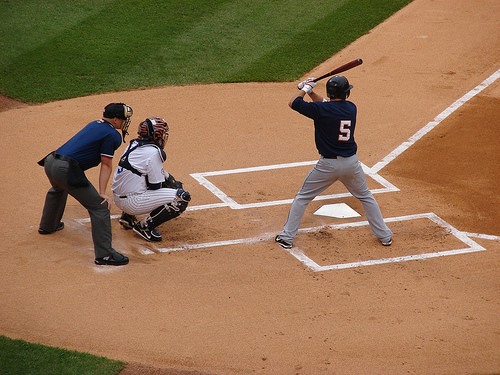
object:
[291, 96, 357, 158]
jersey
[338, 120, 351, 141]
5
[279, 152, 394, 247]
pants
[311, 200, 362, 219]
home plate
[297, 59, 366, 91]
baseball bat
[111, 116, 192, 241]
catcher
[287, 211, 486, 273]
batter's box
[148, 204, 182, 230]
shin guard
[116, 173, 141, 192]
white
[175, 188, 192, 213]
knee pads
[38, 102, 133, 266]
man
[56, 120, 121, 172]
shirt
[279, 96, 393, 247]
uniform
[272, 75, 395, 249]
batter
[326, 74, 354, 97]
helmet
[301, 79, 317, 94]
hands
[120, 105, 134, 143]
face protection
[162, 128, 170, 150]
face protection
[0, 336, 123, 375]
grass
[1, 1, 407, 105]
grass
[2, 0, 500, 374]
ground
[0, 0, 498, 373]
baseball field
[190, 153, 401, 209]
batter's box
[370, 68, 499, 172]
foul line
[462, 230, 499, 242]
foul line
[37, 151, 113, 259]
pants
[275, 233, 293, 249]
shoe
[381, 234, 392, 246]
shoe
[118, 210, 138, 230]
shoe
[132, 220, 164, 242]
shoe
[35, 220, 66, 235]
shoe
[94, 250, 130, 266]
shoe